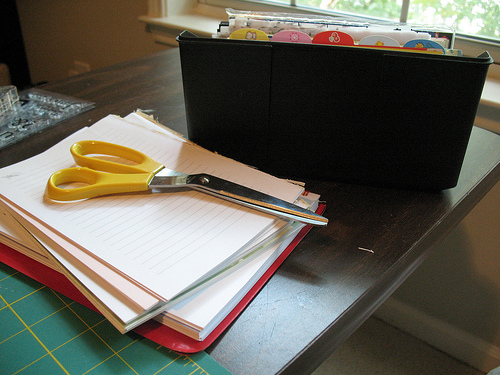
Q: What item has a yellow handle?
A: A scissors.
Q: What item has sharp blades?
A: A scissors.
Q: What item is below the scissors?
A: Paper.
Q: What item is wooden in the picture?
A: The table.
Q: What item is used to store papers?
A: A bin.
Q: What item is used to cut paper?
A: A scissors.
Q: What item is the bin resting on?
A: The table.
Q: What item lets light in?
A: The window.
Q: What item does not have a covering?
A: A window.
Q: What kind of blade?
A: Metal.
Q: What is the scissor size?
A: Large.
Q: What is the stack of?
A: Notebook.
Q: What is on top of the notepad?
A: Scissors.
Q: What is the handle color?
A: Yellow.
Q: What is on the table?
A: Paper.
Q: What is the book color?
A: Red.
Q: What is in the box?
A: Paper.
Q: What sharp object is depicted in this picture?
A: Scissors.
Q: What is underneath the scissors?
A: Stack of paper.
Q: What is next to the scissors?
A: Black organizer.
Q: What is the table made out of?
A: Wood.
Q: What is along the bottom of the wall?
A: White trim.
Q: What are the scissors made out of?
A: Plastic and metal.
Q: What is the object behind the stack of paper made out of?
A: Plastic.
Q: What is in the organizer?
A: Dividers.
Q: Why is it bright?
A: From the window.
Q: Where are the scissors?
A: On the paper.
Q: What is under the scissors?
A: Paper.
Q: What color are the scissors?
A: Yellow and metallic.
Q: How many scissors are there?
A: One pair.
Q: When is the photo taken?
A: Daytime.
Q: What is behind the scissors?
A: A standing file.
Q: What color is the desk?
A: Brown.